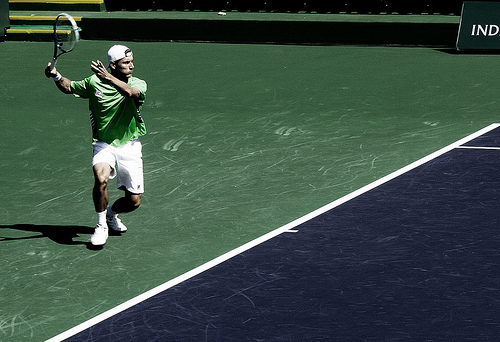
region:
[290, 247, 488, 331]
tennis court is blue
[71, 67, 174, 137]
tennis player's shirt is green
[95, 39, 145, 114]
tennis player wearing ball cap backwards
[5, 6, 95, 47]
steps from the tennis court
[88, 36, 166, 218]
tennis player watching the tennis ball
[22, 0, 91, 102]
tennis racket is held up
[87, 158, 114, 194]
muscles in the player's leg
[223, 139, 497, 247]
outline of the tennis court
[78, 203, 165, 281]
tennis player is wearing white socks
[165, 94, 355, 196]
chalk on the outside of the tennis court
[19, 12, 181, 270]
the man is swinging his raquette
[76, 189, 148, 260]
the man is wearing white tennis shoes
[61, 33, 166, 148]
the man is wearing a green shirt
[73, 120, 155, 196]
the man is wearing white shorts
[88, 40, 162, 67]
the man is wearing a white cap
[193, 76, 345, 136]
the playing surface is green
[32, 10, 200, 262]
the man is playing tennis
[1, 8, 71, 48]
the steps are trimmed in yellow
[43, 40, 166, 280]
the man appears very focused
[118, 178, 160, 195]
there is a tiny logo on the man's shorts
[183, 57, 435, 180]
the court is green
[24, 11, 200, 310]
a player swinging his raquette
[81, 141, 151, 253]
the man has well muscled legs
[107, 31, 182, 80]
the man has his cap turned backward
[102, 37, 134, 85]
the man's cap is white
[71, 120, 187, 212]
the man's shorts are also white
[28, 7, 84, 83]
his raquette appears to be aluminum frame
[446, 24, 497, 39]
the letters "IND" appear in the background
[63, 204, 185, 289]
the player is wearing white sock & shoes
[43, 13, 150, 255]
Man holding tennis racquet in swinging position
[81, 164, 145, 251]
Tennis player's well-muscled legs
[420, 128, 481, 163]
Out of bounds court lines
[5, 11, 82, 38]
green and yellow stairs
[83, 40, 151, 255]
Man wearing green shirt and white shorts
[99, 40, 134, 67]
White baseball cap turned backwards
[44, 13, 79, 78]
Tennis racquet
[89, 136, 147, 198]
white athletic shorts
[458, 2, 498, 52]
Partial view of courtside sign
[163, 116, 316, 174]
Scuffmarks on the court made by shoes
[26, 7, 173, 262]
A man playing tennis.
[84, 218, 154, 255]
Man wearing white tennis shoes.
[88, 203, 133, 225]
Man wearing white socks.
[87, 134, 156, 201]
Man dressed in white tennis shorts.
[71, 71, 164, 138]
Man dressed in green and white t-shirt.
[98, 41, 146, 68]
Man wearing white cap backwards.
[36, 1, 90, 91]
Man holding black and white tennis racket.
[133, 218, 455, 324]
White line on blue and green tennis court.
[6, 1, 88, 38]
Yellow risers on steps.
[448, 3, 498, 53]
Part of a green sign with white writing.